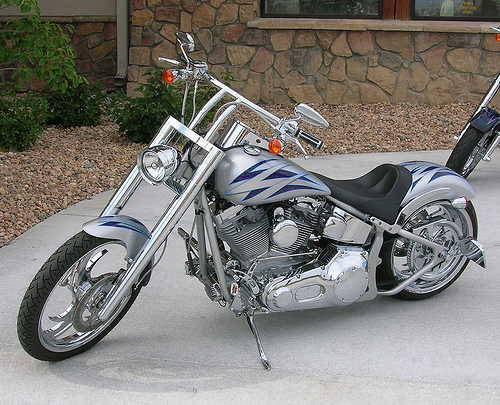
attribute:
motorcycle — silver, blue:
[13, 42, 498, 382]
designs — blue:
[216, 142, 331, 210]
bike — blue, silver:
[15, 38, 493, 379]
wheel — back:
[377, 200, 480, 303]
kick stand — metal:
[247, 311, 272, 377]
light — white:
[130, 140, 182, 188]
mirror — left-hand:
[286, 99, 337, 131]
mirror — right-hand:
[166, 25, 199, 69]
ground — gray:
[2, 141, 498, 402]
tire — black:
[15, 229, 142, 364]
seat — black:
[307, 156, 415, 227]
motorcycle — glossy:
[15, 31, 488, 363]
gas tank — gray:
[210, 140, 332, 209]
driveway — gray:
[0, 150, 498, 401]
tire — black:
[383, 196, 480, 297]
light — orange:
[268, 133, 287, 157]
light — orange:
[163, 66, 184, 87]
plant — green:
[104, 62, 214, 143]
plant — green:
[1, 0, 107, 150]